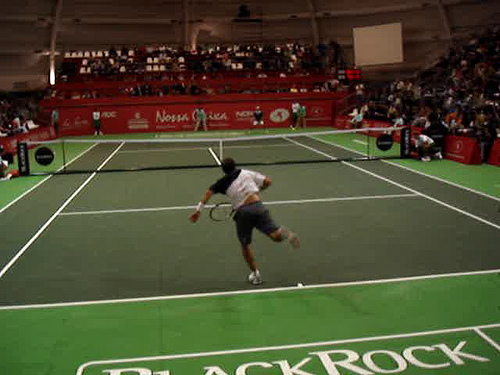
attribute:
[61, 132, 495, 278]
court — green, clay, grey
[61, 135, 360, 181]
net — white, black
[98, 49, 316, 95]
people — watching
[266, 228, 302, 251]
leg — raised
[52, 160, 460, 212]
lines — white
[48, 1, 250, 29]
lights — on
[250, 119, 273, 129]
shorts — white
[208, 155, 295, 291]
player — serving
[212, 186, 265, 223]
racket — black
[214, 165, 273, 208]
shirt — white, black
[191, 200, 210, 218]
wristband — white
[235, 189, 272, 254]
shorts — blue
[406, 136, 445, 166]
ballboy — at match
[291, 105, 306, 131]
linesman — at match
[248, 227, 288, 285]
shoes — white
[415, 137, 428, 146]
shirt — white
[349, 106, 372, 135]
man — running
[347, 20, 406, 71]
screen — white